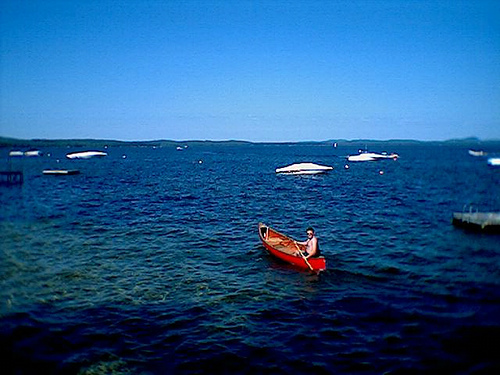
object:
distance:
[0, 0, 499, 154]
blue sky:
[0, 0, 499, 146]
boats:
[8, 148, 45, 160]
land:
[0, 133, 499, 147]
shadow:
[2, 272, 499, 375]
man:
[292, 226, 319, 259]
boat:
[65, 149, 111, 161]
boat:
[9, 150, 43, 158]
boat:
[275, 162, 335, 176]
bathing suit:
[298, 251, 309, 257]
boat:
[346, 151, 399, 163]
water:
[0, 136, 500, 374]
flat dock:
[42, 167, 79, 176]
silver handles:
[462, 202, 484, 213]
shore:
[1, 134, 499, 146]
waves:
[302, 181, 420, 223]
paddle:
[293, 240, 314, 271]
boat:
[254, 221, 327, 274]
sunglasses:
[306, 232, 315, 235]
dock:
[450, 206, 500, 231]